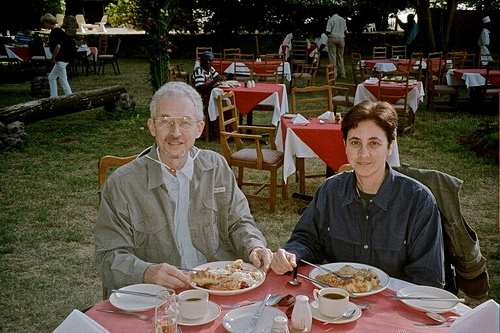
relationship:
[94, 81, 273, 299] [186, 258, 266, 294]
man eating a meal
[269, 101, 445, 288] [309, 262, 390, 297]
lady eating a meal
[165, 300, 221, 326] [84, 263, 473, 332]
saucer on table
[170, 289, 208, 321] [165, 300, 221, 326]
cup on saucer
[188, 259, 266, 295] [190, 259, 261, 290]
plate full of food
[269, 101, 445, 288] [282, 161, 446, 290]
lady wearing a shirt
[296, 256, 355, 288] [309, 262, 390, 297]
silverware on plate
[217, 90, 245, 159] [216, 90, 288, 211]
back of chair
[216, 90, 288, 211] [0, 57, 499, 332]
chair on grass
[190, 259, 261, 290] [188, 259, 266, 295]
food on plate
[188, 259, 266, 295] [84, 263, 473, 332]
plate on table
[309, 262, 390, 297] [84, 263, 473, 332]
plate on table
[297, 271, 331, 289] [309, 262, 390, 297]
butterknife on plate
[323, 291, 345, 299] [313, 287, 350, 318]
coffee in cup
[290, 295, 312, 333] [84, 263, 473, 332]
salt shaker on table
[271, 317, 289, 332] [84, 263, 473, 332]
pepper shaker on table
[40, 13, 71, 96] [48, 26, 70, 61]
woman wearing a shirt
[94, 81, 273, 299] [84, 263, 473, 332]
man sitting at table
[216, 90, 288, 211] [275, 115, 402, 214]
chair at table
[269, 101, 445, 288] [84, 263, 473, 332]
lady eating at table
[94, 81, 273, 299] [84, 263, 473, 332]
man eating at table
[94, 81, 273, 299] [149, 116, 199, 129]
man wearing glasses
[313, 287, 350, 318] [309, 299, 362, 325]
cup on saucer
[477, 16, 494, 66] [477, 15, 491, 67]
person wearing a chef's uniform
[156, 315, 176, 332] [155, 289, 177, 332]
water in glass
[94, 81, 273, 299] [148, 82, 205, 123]
man has hair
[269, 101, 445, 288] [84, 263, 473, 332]
lady sitting at table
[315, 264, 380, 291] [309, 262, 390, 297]
food on plate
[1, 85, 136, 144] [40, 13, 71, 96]
log near woman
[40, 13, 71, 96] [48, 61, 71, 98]
woman wearing pants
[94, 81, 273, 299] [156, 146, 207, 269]
man wearing a shirt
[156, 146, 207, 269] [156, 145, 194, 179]
shirt has a collar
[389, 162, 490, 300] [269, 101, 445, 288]
vest behind lady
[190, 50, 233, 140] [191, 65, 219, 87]
person wearing a shirt